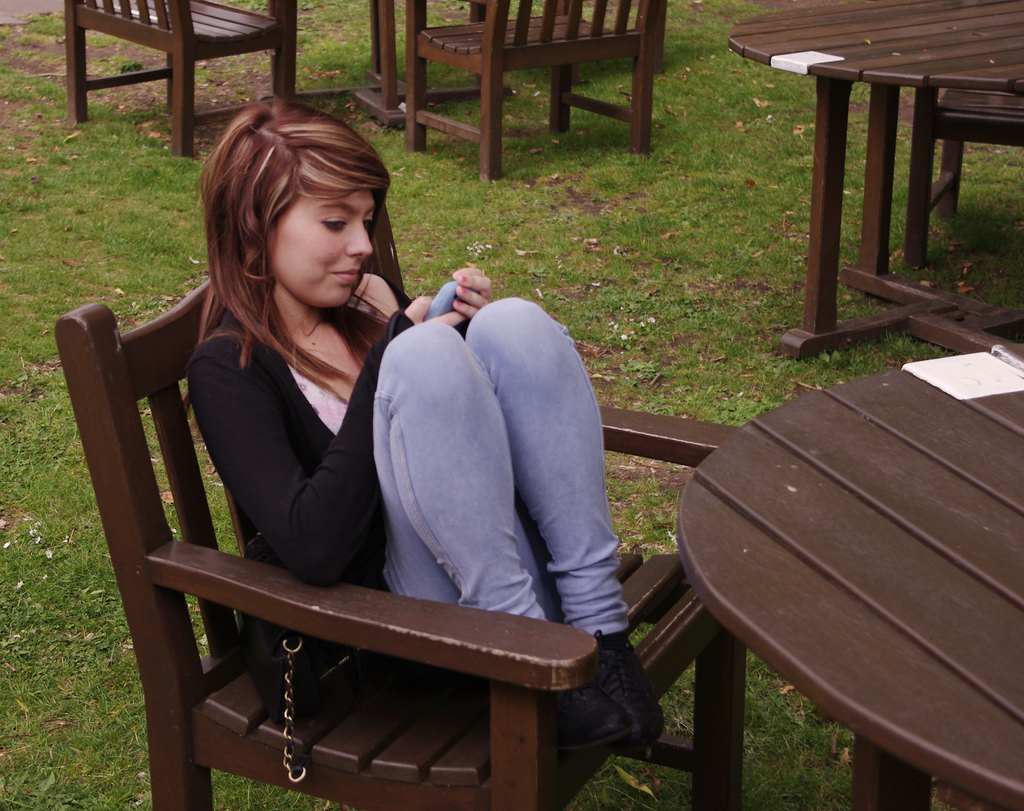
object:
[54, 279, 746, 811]
chair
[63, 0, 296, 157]
chair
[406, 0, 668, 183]
chair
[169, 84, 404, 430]
hair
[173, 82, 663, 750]
girl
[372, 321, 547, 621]
leggins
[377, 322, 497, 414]
knee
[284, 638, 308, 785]
chain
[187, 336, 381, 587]
arm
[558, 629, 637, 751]
shoe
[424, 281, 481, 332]
phone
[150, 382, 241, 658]
panel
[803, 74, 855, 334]
panel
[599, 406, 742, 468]
panel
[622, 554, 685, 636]
panel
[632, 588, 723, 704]
panel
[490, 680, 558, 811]
panel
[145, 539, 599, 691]
panel